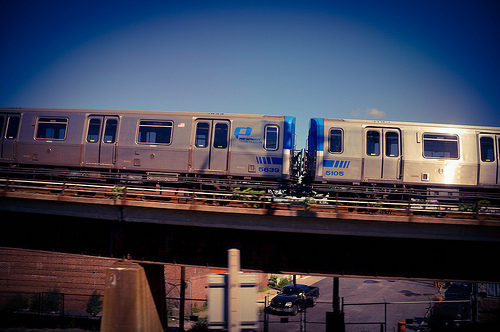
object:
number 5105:
[325, 169, 343, 177]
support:
[97, 257, 167, 331]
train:
[0, 106, 296, 179]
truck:
[264, 284, 322, 316]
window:
[84, 116, 102, 144]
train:
[307, 115, 500, 185]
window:
[213, 121, 229, 149]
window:
[192, 121, 210, 150]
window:
[103, 117, 119, 144]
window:
[3, 113, 20, 141]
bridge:
[0, 190, 500, 243]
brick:
[100, 259, 168, 331]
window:
[480, 135, 496, 164]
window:
[419, 131, 462, 161]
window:
[384, 130, 399, 159]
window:
[366, 130, 380, 156]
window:
[327, 127, 344, 154]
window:
[264, 123, 280, 151]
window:
[135, 117, 173, 144]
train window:
[32, 114, 69, 141]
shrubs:
[231, 186, 266, 208]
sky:
[0, 0, 500, 150]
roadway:
[255, 275, 451, 332]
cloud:
[347, 103, 388, 119]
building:
[0, 248, 212, 331]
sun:
[440, 158, 456, 184]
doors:
[82, 111, 105, 165]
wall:
[0, 248, 128, 331]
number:
[326, 169, 331, 175]